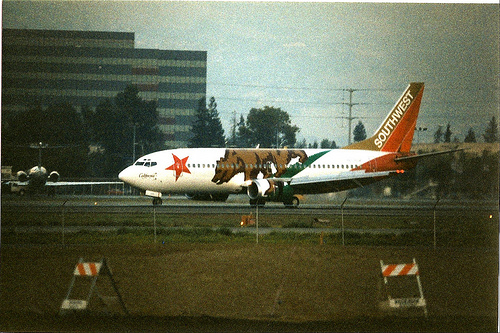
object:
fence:
[1, 188, 498, 251]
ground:
[430, 136, 459, 159]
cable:
[321, 86, 366, 115]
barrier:
[373, 253, 432, 320]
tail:
[343, 76, 424, 155]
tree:
[187, 93, 224, 148]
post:
[61, 256, 127, 313]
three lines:
[253, 81, 483, 123]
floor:
[0, 54, 207, 79]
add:
[280, 165, 408, 200]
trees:
[86, 80, 173, 156]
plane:
[118, 81, 471, 208]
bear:
[212, 143, 307, 195]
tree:
[241, 107, 300, 146]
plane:
[2, 146, 126, 208]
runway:
[21, 187, 118, 208]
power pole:
[343, 85, 357, 147]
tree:
[481, 113, 500, 144]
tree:
[351, 118, 368, 142]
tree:
[6, 103, 93, 173]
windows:
[183, 163, 365, 170]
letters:
[372, 83, 412, 149]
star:
[164, 153, 193, 183]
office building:
[2, 26, 206, 178]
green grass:
[3, 233, 496, 331]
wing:
[272, 166, 408, 194]